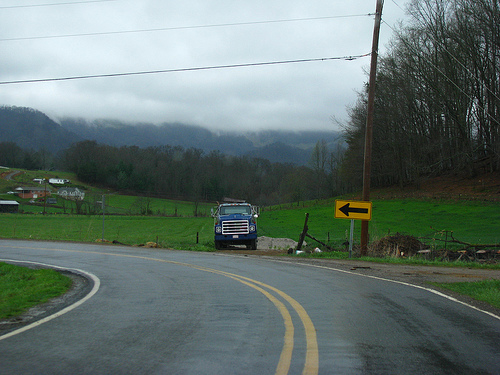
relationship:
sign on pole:
[332, 189, 373, 224] [345, 219, 357, 256]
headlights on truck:
[214, 223, 254, 235] [210, 190, 285, 255]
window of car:
[219, 204, 250, 217] [211, 197, 260, 252]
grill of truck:
[222, 218, 249, 238] [208, 197, 258, 246]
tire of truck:
[246, 240, 258, 251] [214, 201, 259, 251]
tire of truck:
[212, 239, 222, 249] [214, 201, 259, 251]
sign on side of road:
[332, 199, 373, 222] [0, 232, 498, 373]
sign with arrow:
[332, 199, 373, 222] [334, 202, 369, 220]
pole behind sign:
[361, 9, 376, 260] [333, 195, 370, 226]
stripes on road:
[6, 244, 318, 374] [0, 232, 498, 373]